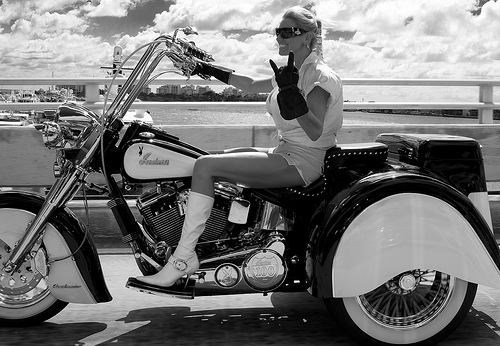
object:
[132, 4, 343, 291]
woman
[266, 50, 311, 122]
black gloves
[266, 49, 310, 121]
gloves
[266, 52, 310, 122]
glove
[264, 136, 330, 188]
shorts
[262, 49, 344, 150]
shirt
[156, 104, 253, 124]
water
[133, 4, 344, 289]
bridge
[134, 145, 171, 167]
logo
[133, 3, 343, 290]
babe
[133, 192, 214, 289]
boots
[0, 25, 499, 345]
3 wheelcycle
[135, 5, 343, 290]
girl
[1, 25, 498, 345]
motorcycle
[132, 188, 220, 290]
boot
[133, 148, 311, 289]
leg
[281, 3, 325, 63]
blond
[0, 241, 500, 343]
road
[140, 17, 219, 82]
handlebars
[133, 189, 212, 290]
white boot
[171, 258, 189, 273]
buckle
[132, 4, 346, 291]
biker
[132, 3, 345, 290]
lady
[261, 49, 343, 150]
top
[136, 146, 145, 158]
logo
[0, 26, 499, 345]
cycle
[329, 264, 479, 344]
wheel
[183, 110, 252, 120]
water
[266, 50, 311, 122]
hand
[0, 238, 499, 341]
tarmac